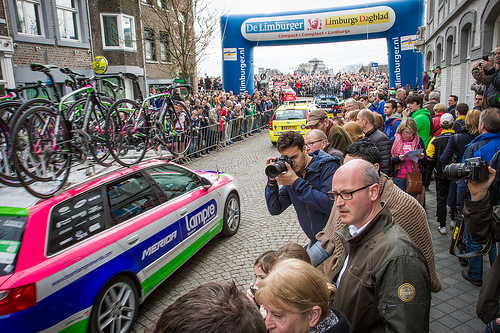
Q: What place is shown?
A: It is a roadside.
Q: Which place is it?
A: It is a roadside.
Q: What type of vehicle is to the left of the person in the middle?
A: The vehicle is a car.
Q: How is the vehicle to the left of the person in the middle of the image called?
A: The vehicle is a car.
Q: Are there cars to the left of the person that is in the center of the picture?
A: Yes, there is a car to the left of the person.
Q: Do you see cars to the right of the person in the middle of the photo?
A: No, the car is to the left of the person.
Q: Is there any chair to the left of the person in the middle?
A: No, there is a car to the left of the person.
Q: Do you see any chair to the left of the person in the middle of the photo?
A: No, there is a car to the left of the person.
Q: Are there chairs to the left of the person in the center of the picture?
A: No, there is a car to the left of the person.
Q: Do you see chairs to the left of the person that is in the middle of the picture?
A: No, there is a car to the left of the person.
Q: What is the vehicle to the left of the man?
A: The vehicle is a car.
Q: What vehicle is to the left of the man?
A: The vehicle is a car.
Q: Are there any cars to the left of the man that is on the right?
A: Yes, there is a car to the left of the man.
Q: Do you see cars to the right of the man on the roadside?
A: No, the car is to the left of the man.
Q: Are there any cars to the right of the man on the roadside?
A: No, the car is to the left of the man.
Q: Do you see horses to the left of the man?
A: No, there is a car to the left of the man.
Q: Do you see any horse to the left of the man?
A: No, there is a car to the left of the man.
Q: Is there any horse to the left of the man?
A: No, there is a car to the left of the man.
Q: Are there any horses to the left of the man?
A: No, there is a car to the left of the man.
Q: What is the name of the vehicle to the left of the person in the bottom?
A: The vehicle is a car.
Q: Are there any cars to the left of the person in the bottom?
A: Yes, there is a car to the left of the person.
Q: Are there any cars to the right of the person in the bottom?
A: No, the car is to the left of the person.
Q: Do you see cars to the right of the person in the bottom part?
A: No, the car is to the left of the person.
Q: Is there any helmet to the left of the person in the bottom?
A: No, there is a car to the left of the person.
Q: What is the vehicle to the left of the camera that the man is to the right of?
A: The vehicle is a car.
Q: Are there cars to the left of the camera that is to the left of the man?
A: Yes, there is a car to the left of the camera.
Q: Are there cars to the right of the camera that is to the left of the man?
A: No, the car is to the left of the camera.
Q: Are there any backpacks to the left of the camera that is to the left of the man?
A: No, there is a car to the left of the camera.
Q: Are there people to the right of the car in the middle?
A: Yes, there is a person to the right of the car.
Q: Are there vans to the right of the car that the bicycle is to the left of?
A: No, there is a person to the right of the car.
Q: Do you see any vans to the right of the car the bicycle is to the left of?
A: No, there is a person to the right of the car.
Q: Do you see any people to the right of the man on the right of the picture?
A: Yes, there is a person to the right of the man.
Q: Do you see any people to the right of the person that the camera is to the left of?
A: Yes, there is a person to the right of the man.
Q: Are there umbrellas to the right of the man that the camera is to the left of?
A: No, there is a person to the right of the man.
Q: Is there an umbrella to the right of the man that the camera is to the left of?
A: No, there is a person to the right of the man.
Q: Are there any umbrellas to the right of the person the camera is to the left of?
A: No, there is a person to the right of the man.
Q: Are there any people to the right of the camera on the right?
A: No, the person is to the left of the camera.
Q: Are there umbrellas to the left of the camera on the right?
A: No, there is a person to the left of the camera.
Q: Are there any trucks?
A: No, there are no trucks.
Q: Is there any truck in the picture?
A: No, there are no trucks.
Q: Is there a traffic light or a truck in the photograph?
A: No, there are no trucks or traffic lights.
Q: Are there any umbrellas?
A: No, there are no umbrellas.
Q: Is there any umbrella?
A: No, there are no umbrellas.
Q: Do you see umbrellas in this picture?
A: No, there are no umbrellas.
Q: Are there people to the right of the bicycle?
A: Yes, there are people to the right of the bicycle.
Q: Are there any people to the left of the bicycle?
A: No, the people are to the right of the bicycle.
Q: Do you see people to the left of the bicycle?
A: No, the people are to the right of the bicycle.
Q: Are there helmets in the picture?
A: No, there are no helmets.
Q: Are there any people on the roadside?
A: Yes, there is a person on the roadside.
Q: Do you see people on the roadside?
A: Yes, there is a person on the roadside.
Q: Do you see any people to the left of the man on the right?
A: Yes, there is a person to the left of the man.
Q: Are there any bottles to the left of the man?
A: No, there is a person to the left of the man.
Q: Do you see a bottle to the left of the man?
A: No, there is a person to the left of the man.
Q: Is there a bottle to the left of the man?
A: No, there is a person to the left of the man.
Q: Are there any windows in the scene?
A: Yes, there is a window.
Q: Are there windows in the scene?
A: Yes, there is a window.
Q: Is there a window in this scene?
A: Yes, there is a window.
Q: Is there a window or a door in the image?
A: Yes, there is a window.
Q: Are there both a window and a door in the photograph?
A: No, there is a window but no doors.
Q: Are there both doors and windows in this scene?
A: No, there is a window but no doors.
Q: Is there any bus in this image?
A: No, there are no buses.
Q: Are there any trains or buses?
A: No, there are no buses or trains.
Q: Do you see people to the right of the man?
A: Yes, there is a person to the right of the man.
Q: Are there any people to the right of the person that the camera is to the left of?
A: Yes, there is a person to the right of the man.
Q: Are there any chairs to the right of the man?
A: No, there is a person to the right of the man.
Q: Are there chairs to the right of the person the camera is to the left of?
A: No, there is a person to the right of the man.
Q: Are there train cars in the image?
A: No, there are no train cars.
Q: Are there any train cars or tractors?
A: No, there are no train cars or tractors.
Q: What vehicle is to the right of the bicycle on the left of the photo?
A: The vehicle is a car.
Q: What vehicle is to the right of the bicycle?
A: The vehicle is a car.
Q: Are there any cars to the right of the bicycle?
A: Yes, there is a car to the right of the bicycle.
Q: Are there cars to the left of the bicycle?
A: No, the car is to the right of the bicycle.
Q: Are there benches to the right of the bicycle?
A: No, there is a car to the right of the bicycle.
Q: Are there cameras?
A: Yes, there is a camera.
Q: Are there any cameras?
A: Yes, there is a camera.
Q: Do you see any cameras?
A: Yes, there is a camera.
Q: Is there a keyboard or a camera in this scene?
A: Yes, there is a camera.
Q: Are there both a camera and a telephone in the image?
A: No, there is a camera but no phones.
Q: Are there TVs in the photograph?
A: No, there are no tvs.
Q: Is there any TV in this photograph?
A: No, there are no televisions.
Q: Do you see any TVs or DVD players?
A: No, there are no TVs or DVD players.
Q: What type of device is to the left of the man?
A: The device is a camera.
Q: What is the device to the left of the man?
A: The device is a camera.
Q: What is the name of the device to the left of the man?
A: The device is a camera.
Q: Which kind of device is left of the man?
A: The device is a camera.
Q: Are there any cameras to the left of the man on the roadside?
A: Yes, there is a camera to the left of the man.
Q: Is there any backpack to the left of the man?
A: No, there is a camera to the left of the man.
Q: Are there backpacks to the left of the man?
A: No, there is a camera to the left of the man.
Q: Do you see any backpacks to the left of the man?
A: No, there is a camera to the left of the man.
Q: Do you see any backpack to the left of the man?
A: No, there is a camera to the left of the man.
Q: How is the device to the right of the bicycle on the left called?
A: The device is a camera.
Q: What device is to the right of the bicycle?
A: The device is a camera.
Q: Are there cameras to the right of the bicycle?
A: Yes, there is a camera to the right of the bicycle.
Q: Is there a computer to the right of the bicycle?
A: No, there is a camera to the right of the bicycle.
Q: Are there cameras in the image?
A: Yes, there is a camera.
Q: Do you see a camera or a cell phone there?
A: Yes, there is a camera.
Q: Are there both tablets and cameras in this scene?
A: No, there is a camera but no tablets.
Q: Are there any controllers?
A: No, there are no controllers.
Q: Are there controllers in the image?
A: No, there are no controllers.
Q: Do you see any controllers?
A: No, there are no controllers.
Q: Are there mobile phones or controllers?
A: No, there are no controllers or mobile phones.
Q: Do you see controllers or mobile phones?
A: No, there are no controllers or mobile phones.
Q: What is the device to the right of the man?
A: The device is a camera.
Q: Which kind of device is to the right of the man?
A: The device is a camera.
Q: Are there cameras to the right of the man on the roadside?
A: Yes, there is a camera to the right of the man.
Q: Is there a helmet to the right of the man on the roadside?
A: No, there is a camera to the right of the man.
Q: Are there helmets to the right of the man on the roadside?
A: No, there is a camera to the right of the man.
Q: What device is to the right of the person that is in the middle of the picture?
A: The device is a camera.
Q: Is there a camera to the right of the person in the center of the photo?
A: Yes, there is a camera to the right of the person.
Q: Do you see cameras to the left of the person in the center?
A: No, the camera is to the right of the person.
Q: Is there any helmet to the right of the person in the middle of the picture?
A: No, there is a camera to the right of the person.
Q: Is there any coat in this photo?
A: Yes, there is a coat.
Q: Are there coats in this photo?
A: Yes, there is a coat.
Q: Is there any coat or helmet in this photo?
A: Yes, there is a coat.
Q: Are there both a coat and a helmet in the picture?
A: No, there is a coat but no helmets.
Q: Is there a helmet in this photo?
A: No, there are no helmets.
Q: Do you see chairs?
A: No, there are no chairs.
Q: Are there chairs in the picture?
A: No, there are no chairs.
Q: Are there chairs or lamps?
A: No, there are no chairs or lamps.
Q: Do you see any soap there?
A: No, there are no soaps.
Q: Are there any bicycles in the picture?
A: Yes, there is a bicycle.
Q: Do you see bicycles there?
A: Yes, there is a bicycle.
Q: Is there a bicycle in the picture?
A: Yes, there is a bicycle.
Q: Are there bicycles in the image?
A: Yes, there is a bicycle.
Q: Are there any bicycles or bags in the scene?
A: Yes, there is a bicycle.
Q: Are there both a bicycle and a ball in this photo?
A: No, there is a bicycle but no balls.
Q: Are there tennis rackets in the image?
A: No, there are no tennis rackets.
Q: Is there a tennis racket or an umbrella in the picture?
A: No, there are no rackets or umbrellas.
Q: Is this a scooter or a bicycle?
A: This is a bicycle.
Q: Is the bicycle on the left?
A: Yes, the bicycle is on the left of the image.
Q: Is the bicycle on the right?
A: No, the bicycle is on the left of the image.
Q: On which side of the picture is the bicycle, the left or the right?
A: The bicycle is on the left of the image.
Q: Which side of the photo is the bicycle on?
A: The bicycle is on the left of the image.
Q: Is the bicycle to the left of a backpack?
A: No, the bicycle is to the left of the car.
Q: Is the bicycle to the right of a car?
A: No, the bicycle is to the left of a car.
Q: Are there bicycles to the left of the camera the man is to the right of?
A: Yes, there is a bicycle to the left of the camera.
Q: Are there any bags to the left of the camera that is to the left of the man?
A: No, there is a bicycle to the left of the camera.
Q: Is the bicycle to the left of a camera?
A: Yes, the bicycle is to the left of a camera.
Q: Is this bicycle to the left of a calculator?
A: No, the bicycle is to the left of a camera.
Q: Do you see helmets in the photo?
A: No, there are no helmets.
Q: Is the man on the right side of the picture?
A: Yes, the man is on the right of the image.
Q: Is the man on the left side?
A: No, the man is on the right of the image.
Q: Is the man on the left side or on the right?
A: The man is on the right of the image.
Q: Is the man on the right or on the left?
A: The man is on the right of the image.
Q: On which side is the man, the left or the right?
A: The man is on the right of the image.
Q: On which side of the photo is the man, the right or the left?
A: The man is on the right of the image.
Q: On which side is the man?
A: The man is on the right of the image.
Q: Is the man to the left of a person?
A: Yes, the man is to the left of a person.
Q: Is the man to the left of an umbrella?
A: No, the man is to the left of a person.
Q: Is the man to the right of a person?
A: No, the man is to the left of a person.